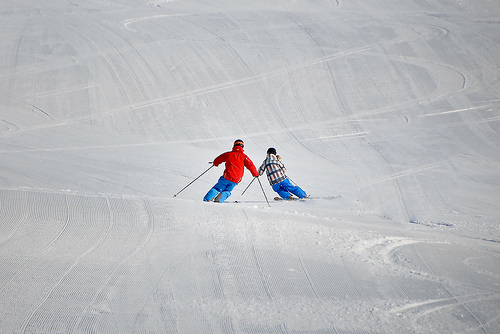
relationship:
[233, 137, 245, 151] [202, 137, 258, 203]
head of man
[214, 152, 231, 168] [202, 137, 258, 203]
arm of man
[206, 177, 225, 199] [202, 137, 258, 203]
leg of man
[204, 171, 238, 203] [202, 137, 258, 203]
pants on man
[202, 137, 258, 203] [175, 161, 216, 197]
man has pole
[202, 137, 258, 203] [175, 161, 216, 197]
man holding pole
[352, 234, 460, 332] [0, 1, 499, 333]
track on slope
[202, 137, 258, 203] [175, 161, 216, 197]
man with pole